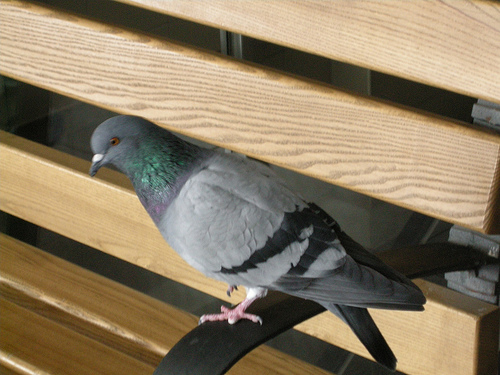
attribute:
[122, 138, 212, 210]
tint — green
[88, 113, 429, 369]
dove — light, grey, black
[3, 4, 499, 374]
bench — brown, wood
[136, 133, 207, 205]
neck — green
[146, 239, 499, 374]
armrest — black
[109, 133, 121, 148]
eye — small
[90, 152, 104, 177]
peak — gray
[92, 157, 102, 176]
beak — black, small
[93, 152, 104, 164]
spot — white